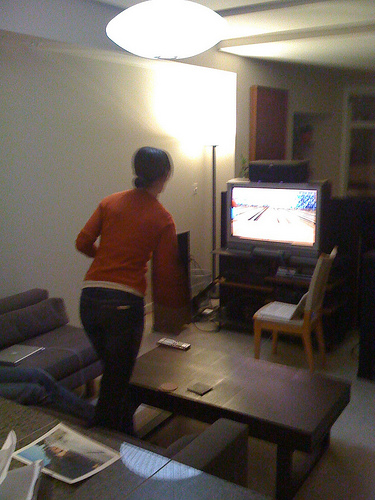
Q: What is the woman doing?
A: Playing video game.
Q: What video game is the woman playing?
A: Nintendo Wii.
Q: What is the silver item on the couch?
A: Laptop.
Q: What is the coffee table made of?
A: Wood.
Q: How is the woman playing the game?
A: Remote control.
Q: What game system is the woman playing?
A: Wii.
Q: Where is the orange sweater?
A: On the standing woman.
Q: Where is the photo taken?
A: Living room.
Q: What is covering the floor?
A: Carpet.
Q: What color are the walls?
A: White.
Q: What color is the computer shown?
A: Silver.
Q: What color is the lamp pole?
A: Black.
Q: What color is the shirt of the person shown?
A: Orange.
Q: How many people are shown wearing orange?
A: One.